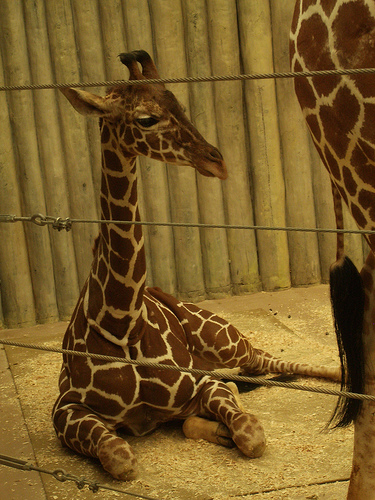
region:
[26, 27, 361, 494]
An animal laying down.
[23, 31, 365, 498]
A giraffe that is brown and white.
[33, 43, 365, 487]
A giraffe that is laying on the ground.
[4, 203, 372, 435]
A gray fence.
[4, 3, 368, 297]
A wall that is behind the giraffe.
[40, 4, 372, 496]
A couple of giraffes.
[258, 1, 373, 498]
A giraffe on the right.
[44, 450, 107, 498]
A hook attachment.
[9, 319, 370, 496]
A gray concrete ground.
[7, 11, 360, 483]
A scene at the zoo.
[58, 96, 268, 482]
giraffe reclined on sawdust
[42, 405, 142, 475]
folded legs of giraffe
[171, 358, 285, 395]
cable on zoo enclosure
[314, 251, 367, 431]
black fur on giraffe tail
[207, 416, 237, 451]
hoof on giraffe foot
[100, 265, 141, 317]
brown spot on giraffe neck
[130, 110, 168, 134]
eye on giraffe head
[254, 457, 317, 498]
sawdust on zoo floor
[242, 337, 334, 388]
outstretched back leg of giraffe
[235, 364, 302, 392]
giraffe tail on ground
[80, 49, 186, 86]
Horn like growths on the head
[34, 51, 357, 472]
A giraffe laying down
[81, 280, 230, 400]
Tan and white spots on giraffe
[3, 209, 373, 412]
Rope enclosing giraffes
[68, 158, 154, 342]
A very long neck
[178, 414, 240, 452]
Hoof-like foot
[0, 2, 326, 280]
Wooden poles in the back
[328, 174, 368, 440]
A tail on a giraffe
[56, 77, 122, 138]
Pointy giraffe ear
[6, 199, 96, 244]
A rope fence latch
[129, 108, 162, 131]
the eye of a giraffe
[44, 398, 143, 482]
the leg of a giraffe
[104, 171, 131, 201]
a brown spot on the giraffe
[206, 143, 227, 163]
a nostril of the giraffe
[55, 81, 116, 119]
the ear of the giraffe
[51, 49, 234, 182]
the head of a giraffe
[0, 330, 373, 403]
a wire from the fence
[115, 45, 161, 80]
the horns of the giraffe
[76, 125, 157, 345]
the neck of the giraffe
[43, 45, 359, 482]
a giraffe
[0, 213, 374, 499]
Three metal cable cord enclosure.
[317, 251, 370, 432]
Long black giraffe tail.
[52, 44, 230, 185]
Baby giraffe's head.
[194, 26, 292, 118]
Section of a wooden wall enclosure.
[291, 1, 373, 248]
Back-end of an adult giraffe.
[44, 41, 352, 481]
Baby Giraffe resting on the ground.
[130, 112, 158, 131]
Baby giraffe's large black eye.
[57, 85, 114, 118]
Baby giraffe's ear.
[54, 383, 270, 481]
Baby giraffe's legs folded on the ground.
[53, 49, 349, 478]
Baby giraffe staying close by mother.